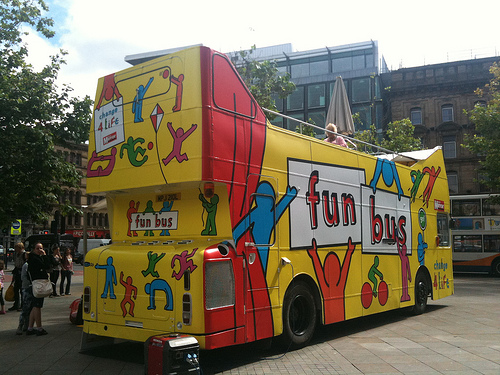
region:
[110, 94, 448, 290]
this is a bus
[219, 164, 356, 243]
the bus has different paints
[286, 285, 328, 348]
this is the wheel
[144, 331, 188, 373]
this is a generator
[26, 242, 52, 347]
this is a lady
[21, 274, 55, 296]
this is a bag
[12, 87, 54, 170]
this is a tree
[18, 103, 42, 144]
the leaves are green in color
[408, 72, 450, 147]
this is a building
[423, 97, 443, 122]
the wall is brown ion color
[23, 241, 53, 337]
woman with a white bag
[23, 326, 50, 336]
black shoes on a woman's foot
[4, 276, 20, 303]
bag in a man's hand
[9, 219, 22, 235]
neon sign with a blue circular design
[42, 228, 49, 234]
red stop light signal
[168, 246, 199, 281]
pink figure on a yellow bus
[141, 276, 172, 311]
blue figure on a yellow bus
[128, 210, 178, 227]
a white design reading fun bus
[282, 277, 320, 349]
black bus wheel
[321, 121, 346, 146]
a woman sitting on the top of a bus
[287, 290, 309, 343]
this is a wheel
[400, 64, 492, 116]
this is a wall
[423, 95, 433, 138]
the wall is brown in color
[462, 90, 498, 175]
this is a tree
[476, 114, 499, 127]
the leaves are green in color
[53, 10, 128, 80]
this is the sky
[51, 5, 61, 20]
the sky is blue in color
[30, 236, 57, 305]
this is a lady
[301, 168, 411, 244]
The logo of the bus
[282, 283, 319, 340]
The rear front tire of the bus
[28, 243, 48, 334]
A woman standing by the bus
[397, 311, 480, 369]
The road beneath the bus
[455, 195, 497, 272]
A bus in front of the Fun Bus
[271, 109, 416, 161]
A railing on top of the bus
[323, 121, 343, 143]
A person on top of the bus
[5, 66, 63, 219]
A green tree near the bus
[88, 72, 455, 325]
A yellow and red bus on the street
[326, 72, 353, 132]
A closed umbrella at the top of the bus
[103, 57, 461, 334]
red and white double decker bus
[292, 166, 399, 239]
red letters on side of bus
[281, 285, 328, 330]
bus has black wheels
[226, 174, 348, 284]
blue human figures on bus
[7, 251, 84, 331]
people are next to bus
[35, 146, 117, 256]
brown building behind bus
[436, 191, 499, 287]
white bus in right rear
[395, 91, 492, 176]
brown building over white bus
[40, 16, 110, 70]
blue and white sky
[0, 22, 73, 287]
green tree left of bus